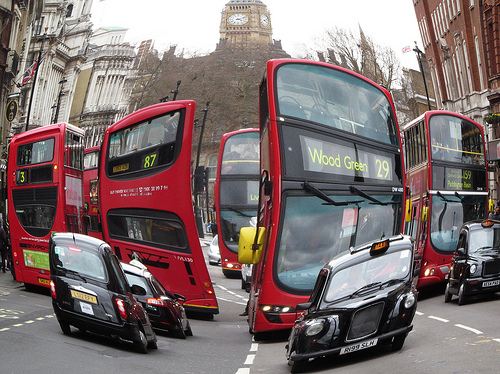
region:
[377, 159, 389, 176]
number 29 on a bus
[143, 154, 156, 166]
number 87 on the back of a bus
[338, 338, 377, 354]
white license plate on a black car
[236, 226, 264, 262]
yellow mirror on a red bus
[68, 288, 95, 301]
yellow license plate on the back of black car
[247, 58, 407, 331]
red bus behind a black car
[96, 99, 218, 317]
red bus in front of a black car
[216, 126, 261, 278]
red bus behind another red bus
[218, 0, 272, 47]
clock tower in the background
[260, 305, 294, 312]
headlight of a red bus turned on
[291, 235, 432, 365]
vehicle on the road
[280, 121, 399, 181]
bus number and route info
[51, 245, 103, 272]
back window of vehicle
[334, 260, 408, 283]
front window of vehicle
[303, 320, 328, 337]
light on the vehicle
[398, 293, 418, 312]
light on the vehicle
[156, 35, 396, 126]
tree tops in the back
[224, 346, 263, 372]
white line on street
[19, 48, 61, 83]
flag hanging off building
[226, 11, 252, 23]
clock on tower of building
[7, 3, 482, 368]
vehicles in front of clocktower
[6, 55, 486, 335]
curved front panels of red double decker buses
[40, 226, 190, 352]
dark cars following rear of buses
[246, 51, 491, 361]
black cars in front of buses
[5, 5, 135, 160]
flat and curved white columns on tan buildings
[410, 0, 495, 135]
white windows and trim on brick building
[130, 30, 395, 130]
leafless tree over bus roofs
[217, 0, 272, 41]
brown building with square panels for clocks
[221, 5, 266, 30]
white clock faces with dark numbers and hands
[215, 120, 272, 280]
curved pole and yellow mirror in front of bus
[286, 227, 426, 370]
Black car on the road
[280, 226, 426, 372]
Black car on the street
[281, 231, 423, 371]
Black car in the road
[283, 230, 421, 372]
Black car in the street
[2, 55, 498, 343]
Buses on the road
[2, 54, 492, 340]
Buses on the street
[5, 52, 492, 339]
Red buses on the road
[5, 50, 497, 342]
Red buses on the street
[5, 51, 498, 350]
Double decker buses on the road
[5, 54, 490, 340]
Double decker buses on the street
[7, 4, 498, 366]
distorted image of England city street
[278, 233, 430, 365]
car in the road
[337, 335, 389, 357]
license on a car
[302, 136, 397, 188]
route on a bus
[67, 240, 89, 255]
brake light on a car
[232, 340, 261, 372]
white dashes painted on street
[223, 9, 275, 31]
clocks on a tower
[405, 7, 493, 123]
buildings on side of road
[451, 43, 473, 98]
windows on a building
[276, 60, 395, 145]
window on a bus